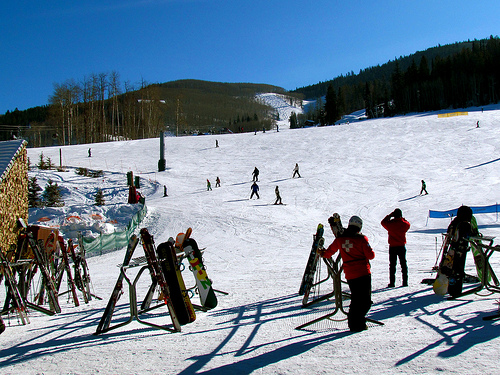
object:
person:
[273, 185, 283, 206]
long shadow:
[191, 329, 364, 375]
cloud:
[0, 1, 499, 92]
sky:
[0, 1, 500, 116]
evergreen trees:
[324, 83, 341, 126]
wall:
[76, 190, 148, 257]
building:
[1, 139, 31, 260]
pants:
[343, 272, 373, 332]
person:
[317, 215, 377, 333]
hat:
[348, 214, 363, 232]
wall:
[0, 143, 31, 263]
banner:
[430, 203, 500, 218]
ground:
[0, 89, 500, 374]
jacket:
[380, 212, 411, 246]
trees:
[169, 79, 186, 138]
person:
[416, 179, 429, 197]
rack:
[91, 228, 230, 336]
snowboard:
[182, 238, 219, 310]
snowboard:
[154, 242, 198, 325]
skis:
[102, 239, 138, 333]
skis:
[144, 230, 183, 333]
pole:
[157, 128, 167, 173]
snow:
[6, 94, 500, 375]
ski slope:
[12, 110, 500, 372]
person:
[476, 121, 481, 129]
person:
[291, 162, 302, 178]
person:
[249, 181, 260, 199]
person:
[251, 166, 260, 182]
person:
[214, 176, 221, 188]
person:
[206, 178, 213, 192]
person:
[214, 139, 219, 148]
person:
[85, 146, 92, 156]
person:
[380, 207, 412, 290]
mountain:
[291, 30, 500, 113]